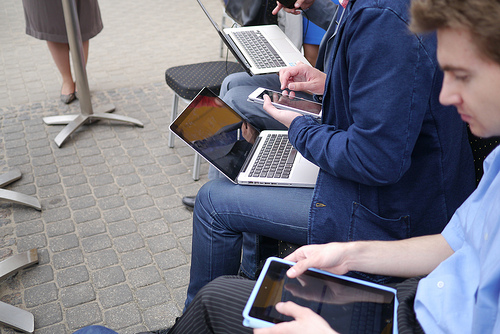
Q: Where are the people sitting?
A: On chairs.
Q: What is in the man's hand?
A: A tablet.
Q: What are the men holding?
A: Computers.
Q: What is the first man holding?
A: Tablet.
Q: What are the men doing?
A: Sitting.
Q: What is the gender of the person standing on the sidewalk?
A: Female.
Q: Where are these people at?
A: Sidewalk.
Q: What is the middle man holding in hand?
A: Cell phone.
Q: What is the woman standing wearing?
A: Skirt.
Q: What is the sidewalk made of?
A: Brick.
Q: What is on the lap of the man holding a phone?
A: A laptop.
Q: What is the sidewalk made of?
A: Concrete pavers.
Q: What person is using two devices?
A: The man in the middle.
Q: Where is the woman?
A: Standing behind the table.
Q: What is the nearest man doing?
A: Looking at his tablet.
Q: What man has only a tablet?
A: The man in the blue shirt.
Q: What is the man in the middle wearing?
A: Jeans and a blue coat.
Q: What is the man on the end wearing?
A: A light blue shirt.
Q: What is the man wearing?
A: Blue jeans of man wearing blue jacket.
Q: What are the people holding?
A: Two people with laptops.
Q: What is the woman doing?
A: Lectern woman is standing behind.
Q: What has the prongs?
A: A stand on street.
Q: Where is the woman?
A: Woman in front a stand.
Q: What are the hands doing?
A: Hands holding a tablet.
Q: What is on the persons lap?
A: A laptop on lap of person.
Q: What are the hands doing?
A: Hands holding a tablet.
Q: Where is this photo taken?
A: Outside in public.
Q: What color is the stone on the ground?
A: Gray.